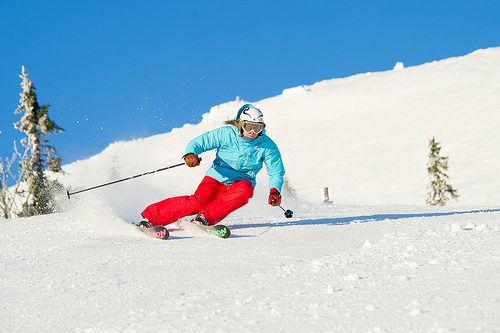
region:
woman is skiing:
[50, 72, 338, 265]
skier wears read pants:
[50, 80, 346, 250]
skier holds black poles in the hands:
[55, 100, 320, 245]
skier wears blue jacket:
[55, 80, 310, 250]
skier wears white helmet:
[63, 85, 320, 270]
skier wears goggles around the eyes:
[116, 92, 306, 242]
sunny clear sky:
[0, 3, 490, 206]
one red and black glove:
[250, 171, 320, 221]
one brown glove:
[175, 145, 210, 180]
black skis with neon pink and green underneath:
[117, 207, 270, 249]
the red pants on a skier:
[138, 186, 246, 226]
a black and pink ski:
[135, 212, 170, 240]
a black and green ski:
[190, 219, 236, 241]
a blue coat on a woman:
[201, 131, 281, 186]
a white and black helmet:
[238, 103, 269, 133]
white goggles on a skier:
[241, 120, 267, 134]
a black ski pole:
[56, 147, 225, 201]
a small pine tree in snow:
[413, 132, 468, 208]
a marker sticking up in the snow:
[316, 182, 336, 206]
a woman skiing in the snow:
[98, 78, 320, 278]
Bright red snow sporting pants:
[133, 170, 259, 247]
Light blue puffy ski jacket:
[170, 112, 293, 204]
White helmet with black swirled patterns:
[225, 97, 272, 152]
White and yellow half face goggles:
[236, 112, 270, 144]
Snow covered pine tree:
[391, 117, 474, 244]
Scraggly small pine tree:
[0, 60, 77, 220]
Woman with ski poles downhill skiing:
[127, 65, 312, 271]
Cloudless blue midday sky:
[4, 2, 496, 191]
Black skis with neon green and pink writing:
[128, 217, 253, 251]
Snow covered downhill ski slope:
[0, 37, 487, 231]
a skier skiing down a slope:
[130, 81, 308, 241]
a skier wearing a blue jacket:
[112, 77, 326, 248]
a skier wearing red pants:
[125, 80, 310, 254]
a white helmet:
[228, 90, 299, 138]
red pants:
[132, 165, 286, 242]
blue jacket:
[157, 112, 301, 192]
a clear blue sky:
[52, 18, 239, 73]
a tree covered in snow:
[14, 50, 78, 218]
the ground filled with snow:
[77, 235, 447, 307]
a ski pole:
[52, 160, 257, 208]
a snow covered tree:
[405, 114, 475, 216]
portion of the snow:
[261, 247, 401, 320]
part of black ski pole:
[62, 165, 162, 195]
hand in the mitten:
[269, 187, 284, 205]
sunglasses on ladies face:
[241, 117, 263, 133]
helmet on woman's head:
[242, 102, 267, 121]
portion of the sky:
[77, 41, 235, 95]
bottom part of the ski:
[205, 224, 234, 241]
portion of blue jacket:
[223, 137, 252, 171]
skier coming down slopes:
[60, 104, 303, 250]